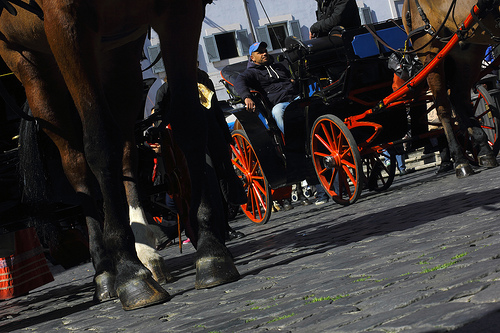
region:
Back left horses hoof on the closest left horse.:
[91, 268, 118, 300]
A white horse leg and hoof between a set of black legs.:
[121, 164, 172, 284]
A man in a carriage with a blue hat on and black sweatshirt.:
[231, 40, 303, 137]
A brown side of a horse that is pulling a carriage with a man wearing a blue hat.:
[398, 1, 499, 177]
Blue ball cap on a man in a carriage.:
[245, 40, 269, 54]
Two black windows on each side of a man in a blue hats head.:
[210, 20, 295, 60]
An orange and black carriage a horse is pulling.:
[215, 61, 399, 224]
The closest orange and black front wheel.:
[306, 113, 363, 205]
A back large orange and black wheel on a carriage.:
[228, 125, 273, 225]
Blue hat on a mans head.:
[246, 40, 266, 61]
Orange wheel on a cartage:
[302, 115, 365, 193]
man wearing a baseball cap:
[241, 35, 268, 53]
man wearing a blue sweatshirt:
[242, 63, 286, 102]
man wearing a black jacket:
[308, 4, 353, 31]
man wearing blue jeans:
[271, 97, 295, 121]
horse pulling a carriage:
[411, 18, 497, 128]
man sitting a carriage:
[241, 58, 317, 133]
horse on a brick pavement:
[50, 99, 247, 295]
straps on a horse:
[409, 13, 457, 48]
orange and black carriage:
[234, 95, 394, 162]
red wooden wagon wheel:
[307, 111, 362, 208]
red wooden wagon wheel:
[221, 132, 278, 224]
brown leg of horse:
[401, 19, 472, 179]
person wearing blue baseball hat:
[244, 40, 271, 56]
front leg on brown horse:
[37, 5, 169, 305]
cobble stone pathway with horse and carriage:
[29, 203, 487, 325]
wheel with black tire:
[307, 112, 367, 207]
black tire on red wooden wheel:
[219, 126, 275, 221]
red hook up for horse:
[334, 5, 484, 129]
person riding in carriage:
[235, 35, 307, 142]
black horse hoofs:
[85, 230, 245, 310]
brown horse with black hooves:
[1, 0, 247, 312]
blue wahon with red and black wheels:
[214, 12, 429, 229]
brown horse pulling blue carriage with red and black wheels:
[216, 0, 441, 230]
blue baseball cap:
[240, 36, 268, 57]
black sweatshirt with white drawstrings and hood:
[230, 57, 300, 107]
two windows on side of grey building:
[205, 16, 302, 61]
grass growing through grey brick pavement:
[287, 280, 364, 312]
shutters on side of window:
[200, 31, 224, 68]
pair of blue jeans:
[261, 91, 306, 138]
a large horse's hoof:
[191, 210, 240, 288]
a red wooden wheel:
[305, 119, 364, 206]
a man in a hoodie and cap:
[235, 40, 294, 134]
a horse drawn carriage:
[220, 7, 497, 214]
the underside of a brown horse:
[0, 0, 237, 291]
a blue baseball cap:
[250, 40, 267, 50]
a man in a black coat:
[308, 0, 362, 43]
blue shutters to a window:
[205, 33, 218, 63]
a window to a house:
[217, 30, 237, 57]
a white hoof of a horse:
[130, 199, 162, 281]